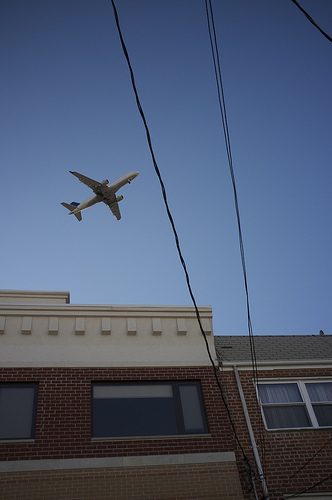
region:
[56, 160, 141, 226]
airplane flying in the sky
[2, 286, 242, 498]
a brick styled building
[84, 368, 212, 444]
windows of a building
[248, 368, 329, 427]
windows of a building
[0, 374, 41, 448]
windows of a building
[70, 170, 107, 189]
wing span of an airplane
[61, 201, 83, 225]
back fins of an airplane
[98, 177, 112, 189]
engine of an airplane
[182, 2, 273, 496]
power lines across from building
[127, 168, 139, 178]
cockpit of airplane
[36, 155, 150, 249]
the plane is flying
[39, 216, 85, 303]
the sky is clear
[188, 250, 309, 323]
the sky is clear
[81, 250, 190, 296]
the sky is clear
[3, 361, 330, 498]
a red brick building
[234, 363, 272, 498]
a pole running up the side of a building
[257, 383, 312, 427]
a curtain inside a window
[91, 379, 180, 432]
a window in a building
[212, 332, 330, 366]
a grey shingled roof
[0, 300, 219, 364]
a parapet wall on a building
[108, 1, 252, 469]
a black wire running from a building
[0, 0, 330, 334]
a clear blue sky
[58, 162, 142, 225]
an airplane in the sky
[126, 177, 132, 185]
the nose wheel of an airplane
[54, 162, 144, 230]
large white plane flying in sky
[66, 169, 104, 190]
long white wing of plane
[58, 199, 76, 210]
small tail fin of plane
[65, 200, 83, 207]
blue tail fin of plane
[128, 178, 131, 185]
front landing wheel of plane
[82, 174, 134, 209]
bottom of large plane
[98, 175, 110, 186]
jet engine on plane wing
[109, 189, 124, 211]
jet engine on wing of plane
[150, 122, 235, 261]
black power lines in the air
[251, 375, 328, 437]
white windows on brick building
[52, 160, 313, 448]
a jet flying over a neighborhood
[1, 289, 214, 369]
a decorative parapet is on the building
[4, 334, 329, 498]
the apartment buildings are red brick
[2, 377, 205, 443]
the window frames are black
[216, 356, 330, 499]
a gutter is on a building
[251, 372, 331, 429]
the window frame is white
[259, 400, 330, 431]
screens are on the windows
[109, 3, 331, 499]
wires are running from the building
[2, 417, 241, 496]
a beige brick is under the windows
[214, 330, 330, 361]
the roof has gray shingles